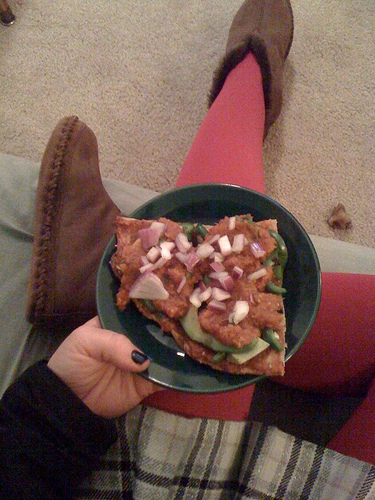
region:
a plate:
[70, 139, 328, 411]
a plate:
[129, 173, 285, 383]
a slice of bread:
[95, 151, 342, 385]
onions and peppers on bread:
[85, 253, 350, 427]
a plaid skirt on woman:
[180, 402, 360, 468]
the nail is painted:
[94, 330, 214, 408]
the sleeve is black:
[16, 344, 142, 436]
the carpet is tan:
[31, 98, 226, 275]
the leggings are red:
[183, 19, 370, 144]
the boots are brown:
[173, 29, 346, 151]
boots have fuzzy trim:
[207, 44, 353, 179]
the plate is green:
[81, 206, 260, 329]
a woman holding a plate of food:
[35, 180, 336, 449]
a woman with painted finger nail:
[77, 323, 162, 413]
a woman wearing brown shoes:
[151, 13, 305, 137]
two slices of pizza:
[96, 204, 289, 373]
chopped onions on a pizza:
[92, 234, 257, 338]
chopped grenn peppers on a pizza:
[169, 218, 288, 343]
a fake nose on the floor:
[319, 192, 350, 238]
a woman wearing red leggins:
[113, 80, 313, 480]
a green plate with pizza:
[100, 210, 320, 405]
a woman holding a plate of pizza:
[51, 162, 329, 472]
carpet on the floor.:
[74, 30, 138, 62]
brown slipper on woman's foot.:
[65, 174, 100, 282]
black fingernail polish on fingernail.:
[131, 351, 144, 361]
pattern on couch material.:
[174, 441, 217, 469]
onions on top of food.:
[192, 243, 227, 267]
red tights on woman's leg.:
[334, 294, 364, 364]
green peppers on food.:
[273, 266, 283, 293]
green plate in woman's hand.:
[295, 229, 310, 297]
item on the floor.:
[330, 201, 358, 234]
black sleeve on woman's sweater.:
[31, 396, 66, 431]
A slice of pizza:
[150, 246, 221, 381]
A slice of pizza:
[185, 199, 264, 380]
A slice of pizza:
[208, 294, 286, 490]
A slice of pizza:
[186, 323, 248, 496]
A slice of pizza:
[206, 238, 293, 426]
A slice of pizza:
[176, 238, 260, 493]